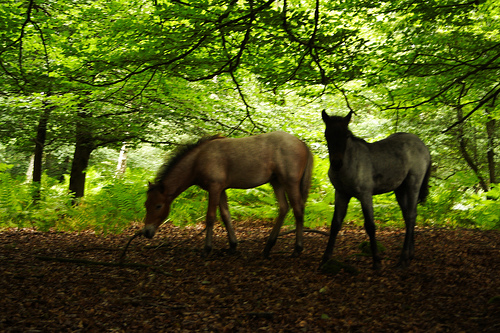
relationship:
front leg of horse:
[316, 187, 351, 274] [311, 100, 438, 274]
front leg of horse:
[358, 192, 385, 270] [311, 100, 438, 274]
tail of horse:
[423, 160, 434, 206] [295, 103, 433, 263]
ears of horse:
[319, 107, 354, 120] [311, 100, 438, 274]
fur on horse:
[154, 132, 219, 182] [142, 124, 316, 251]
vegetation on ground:
[40, 188, 132, 234] [10, 174, 388, 330]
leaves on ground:
[0, 224, 500, 330] [5, 202, 479, 327]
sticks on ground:
[26, 220, 312, 314] [7, 221, 483, 322]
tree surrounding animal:
[55, 13, 116, 209] [319, 109, 431, 280]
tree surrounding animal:
[17, 59, 64, 209] [140, 128, 315, 266]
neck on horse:
[156, 144, 201, 209] [81, 102, 318, 288]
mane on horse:
[146, 130, 224, 194] [131, 126, 316, 268]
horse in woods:
[141, 131, 315, 256] [3, 4, 497, 331]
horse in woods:
[317, 106, 429, 268] [3, 4, 497, 331]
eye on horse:
[155, 199, 167, 214] [142, 124, 316, 251]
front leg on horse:
[357, 190, 381, 271] [311, 100, 438, 274]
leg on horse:
[287, 197, 309, 257] [311, 100, 438, 274]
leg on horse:
[258, 190, 289, 254] [311, 100, 438, 274]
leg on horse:
[220, 203, 242, 248] [311, 100, 438, 274]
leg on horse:
[198, 194, 220, 252] [142, 124, 316, 251]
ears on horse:
[303, 99, 366, 124] [311, 100, 438, 274]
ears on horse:
[321, 109, 330, 123] [311, 100, 438, 274]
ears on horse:
[145, 177, 161, 195] [142, 124, 316, 251]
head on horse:
[139, 174, 176, 239] [134, 126, 319, 238]